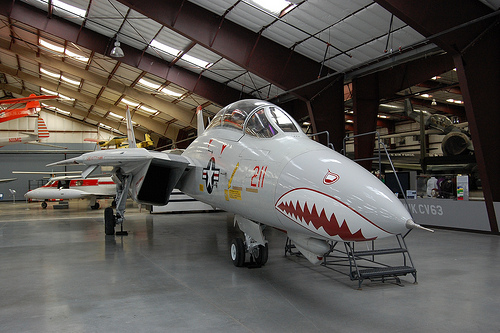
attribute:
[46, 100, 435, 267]
jet — painted, grey, gray, parked, fighter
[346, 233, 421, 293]
metal steps — gray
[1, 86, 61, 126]
plane — red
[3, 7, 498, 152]
roof — large, slanted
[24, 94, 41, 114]
tail wing — red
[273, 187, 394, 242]
paint — red, white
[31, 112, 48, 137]
tail wing — red, white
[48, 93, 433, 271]
planes — jet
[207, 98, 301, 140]
windshield — clear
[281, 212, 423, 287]
ladder — grey, metal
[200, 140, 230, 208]
star — white, black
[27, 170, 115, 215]
plane — red, white